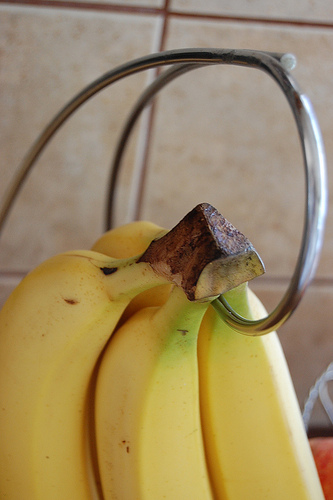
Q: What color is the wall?
A: Tan.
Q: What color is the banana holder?
A: Silver.